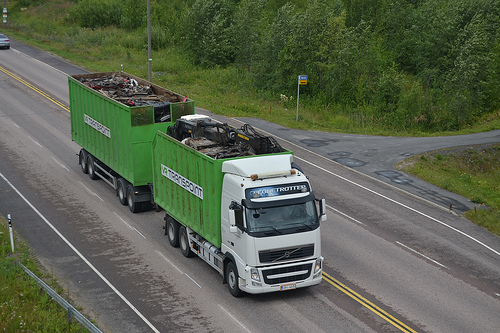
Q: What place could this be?
A: It is a highway.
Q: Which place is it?
A: It is a highway.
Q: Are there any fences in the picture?
A: No, there are no fences.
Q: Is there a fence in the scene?
A: No, there are no fences.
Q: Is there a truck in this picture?
A: Yes, there is a truck.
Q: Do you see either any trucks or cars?
A: Yes, there is a truck.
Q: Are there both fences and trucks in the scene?
A: No, there is a truck but no fences.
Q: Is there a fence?
A: No, there are no fences.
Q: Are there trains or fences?
A: No, there are no fences or trains.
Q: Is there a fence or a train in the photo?
A: No, there are no fences or trains.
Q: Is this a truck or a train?
A: This is a truck.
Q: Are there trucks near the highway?
A: Yes, there is a truck near the highway.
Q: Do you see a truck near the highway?
A: Yes, there is a truck near the highway.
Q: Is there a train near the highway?
A: No, there is a truck near the highway.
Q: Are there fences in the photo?
A: No, there are no fences.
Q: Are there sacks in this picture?
A: No, there are no sacks.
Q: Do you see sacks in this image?
A: No, there are no sacks.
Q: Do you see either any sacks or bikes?
A: No, there are no sacks or bikes.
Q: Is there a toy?
A: No, there are no toys.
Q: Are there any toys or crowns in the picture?
A: No, there are no toys or crowns.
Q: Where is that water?
A: The water is on the highway.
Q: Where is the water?
A: The water is on the highway.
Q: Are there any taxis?
A: Yes, there is a taxi.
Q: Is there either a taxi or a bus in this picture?
A: Yes, there is a taxi.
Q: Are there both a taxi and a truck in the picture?
A: Yes, there are both a taxi and a truck.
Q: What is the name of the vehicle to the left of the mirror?
A: The vehicle is a taxi.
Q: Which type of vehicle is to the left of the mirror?
A: The vehicle is a taxi.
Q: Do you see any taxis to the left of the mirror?
A: Yes, there is a taxi to the left of the mirror.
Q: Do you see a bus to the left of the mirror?
A: No, there is a taxi to the left of the mirror.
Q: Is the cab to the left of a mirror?
A: Yes, the cab is to the left of a mirror.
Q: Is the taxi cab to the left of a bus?
A: No, the taxi cab is to the left of a mirror.